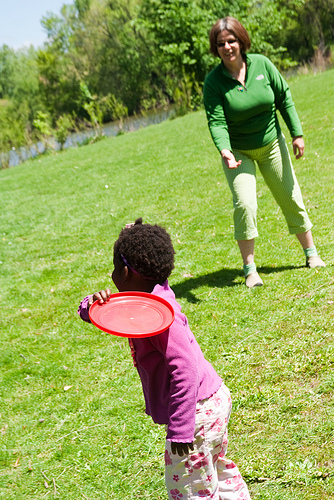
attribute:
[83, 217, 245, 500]
child — small, playing, standing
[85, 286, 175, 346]
frisbee — red, bright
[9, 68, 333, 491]
grass — green, greenb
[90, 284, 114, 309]
hand — girl's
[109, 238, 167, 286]
headband — purple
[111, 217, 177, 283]
hair — girl's, brown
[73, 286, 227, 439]
shirt — purple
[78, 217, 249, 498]
girl — little, getting ready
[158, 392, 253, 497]
pants — white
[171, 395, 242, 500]
flowers — purple, pink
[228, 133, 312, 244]
capris — light green, green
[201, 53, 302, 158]
shirt — dark green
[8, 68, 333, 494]
field — green, grassy, here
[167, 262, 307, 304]
shadow — woman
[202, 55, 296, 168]
sweater — here, green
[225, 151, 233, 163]
finger — here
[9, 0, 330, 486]
garden — here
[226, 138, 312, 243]
trouser — here'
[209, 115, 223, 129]
elbow — here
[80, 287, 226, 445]
sweater — pink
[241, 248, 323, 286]
socks — green